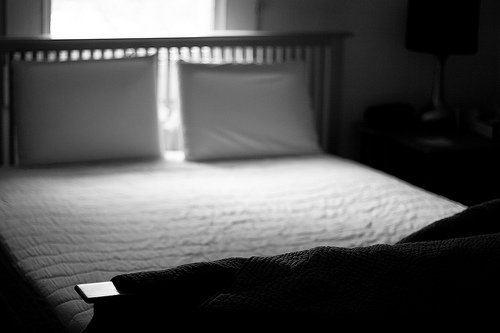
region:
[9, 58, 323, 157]
two pillows propped on the bed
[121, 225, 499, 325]
blanket draped over footboard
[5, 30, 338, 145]
headboard in front of the window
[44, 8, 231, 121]
window behind the bed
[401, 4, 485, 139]
lamp on bedside table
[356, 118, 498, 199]
table beside the bed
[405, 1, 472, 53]
shade on the lamp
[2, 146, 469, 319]
white blanket on the bed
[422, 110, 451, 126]
base of the lamp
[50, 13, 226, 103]
sunlight coming through the window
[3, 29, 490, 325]
a bed in the room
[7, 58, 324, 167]
pillows on the bed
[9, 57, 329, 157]
the pillows are white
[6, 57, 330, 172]
the amount of pillows are two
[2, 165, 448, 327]
sheets on the bed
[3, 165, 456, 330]
the sheet is white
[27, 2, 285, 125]
a window behind the bed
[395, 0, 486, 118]
a lamp on the side of the bed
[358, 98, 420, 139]
an alarm clock on the side of the bed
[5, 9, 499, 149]
the walls of the room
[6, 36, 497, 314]
the bed is made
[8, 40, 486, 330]
the bed looks clean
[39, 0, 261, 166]
the window is open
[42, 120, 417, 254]
sunlight shines on the bed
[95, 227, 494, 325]
a blanket is draped over the front of the bed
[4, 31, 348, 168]
the pillows are leaning on the headboard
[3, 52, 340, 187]
the pillowcases are white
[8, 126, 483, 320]
the comforter is white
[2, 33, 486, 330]
the headboard and footboard are made of wood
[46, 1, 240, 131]
there are no curtains or blinds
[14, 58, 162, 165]
A pillow on a bed.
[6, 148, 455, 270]
A white sheet on the bed.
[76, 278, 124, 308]
A piece of the footboard.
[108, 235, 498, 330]
A black comforter at the foot of the bed.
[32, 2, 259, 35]
Light streams through the window.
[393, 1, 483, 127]
A lamp on a table.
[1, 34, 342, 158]
Two pillow propped up against the headboard.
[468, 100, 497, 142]
Items on the bedside table.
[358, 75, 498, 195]
A small bedside table.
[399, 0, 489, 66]
The square shade of the lamp.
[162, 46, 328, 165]
white pillow on a bed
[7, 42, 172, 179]
white pillow on a bed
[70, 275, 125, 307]
corner of wooden footboard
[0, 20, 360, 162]
wooden headboard on the bed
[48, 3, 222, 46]
window behind the bed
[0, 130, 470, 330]
white sheet on the bed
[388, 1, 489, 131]
lamp near the bed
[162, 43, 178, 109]
wooden slat on the headboard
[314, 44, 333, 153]
wooden slat on the headboard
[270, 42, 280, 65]
wooden slat on the headboard